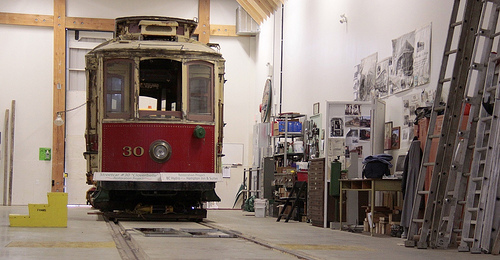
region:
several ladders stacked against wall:
[402, 0, 499, 252]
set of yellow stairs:
[9, 188, 69, 228]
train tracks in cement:
[103, 213, 310, 259]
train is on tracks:
[85, 14, 225, 219]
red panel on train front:
[96, 119, 218, 185]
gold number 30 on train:
[119, 145, 145, 156]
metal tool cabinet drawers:
[306, 160, 326, 228]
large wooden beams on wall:
[1, 3, 256, 190]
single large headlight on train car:
[148, 138, 172, 163]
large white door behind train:
[66, 25, 198, 205]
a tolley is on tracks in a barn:
[6, 2, 498, 252]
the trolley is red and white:
[82, 12, 228, 202]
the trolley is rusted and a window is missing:
[81, 18, 226, 191]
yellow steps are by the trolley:
[6, 183, 75, 234]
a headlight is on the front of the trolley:
[143, 135, 180, 165]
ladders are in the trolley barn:
[401, 2, 498, 252]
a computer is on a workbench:
[337, 148, 412, 238]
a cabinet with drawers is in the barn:
[303, 152, 330, 231]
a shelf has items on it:
[269, 108, 304, 218]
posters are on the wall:
[347, 23, 433, 113]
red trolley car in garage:
[80, 8, 233, 234]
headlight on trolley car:
[146, 137, 171, 164]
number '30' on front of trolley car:
[118, 140, 144, 160]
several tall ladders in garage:
[397, 3, 496, 258]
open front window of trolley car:
[127, 49, 191, 125]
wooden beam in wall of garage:
[47, 2, 70, 198]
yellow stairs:
[2, 187, 76, 235]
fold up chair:
[267, 173, 314, 229]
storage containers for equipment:
[235, 93, 403, 240]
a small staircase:
[6, 170, 107, 246]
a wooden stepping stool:
[3, 170, 98, 243]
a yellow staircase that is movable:
[3, 187, 98, 238]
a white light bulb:
[44, 105, 74, 135]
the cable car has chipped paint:
[76, 6, 269, 226]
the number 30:
[116, 136, 145, 163]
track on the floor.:
[120, 233, 134, 253]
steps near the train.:
[28, 201, 59, 223]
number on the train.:
[123, 144, 142, 158]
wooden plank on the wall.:
[10, 15, 52, 22]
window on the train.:
[192, 74, 207, 104]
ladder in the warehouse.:
[457, 152, 492, 234]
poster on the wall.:
[393, 33, 427, 84]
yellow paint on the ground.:
[37, 241, 107, 248]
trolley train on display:
[83, 12, 230, 222]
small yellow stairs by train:
[5, 182, 72, 233]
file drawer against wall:
[299, 149, 331, 226]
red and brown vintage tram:
[103, 27, 204, 233]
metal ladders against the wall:
[416, 13, 489, 258]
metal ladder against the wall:
[437, 23, 459, 124]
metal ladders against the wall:
[476, 85, 496, 195]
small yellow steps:
[11, 194, 69, 224]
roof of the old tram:
[114, 14, 204, 44]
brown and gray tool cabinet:
[308, 157, 334, 229]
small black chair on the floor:
[275, 174, 309, 221]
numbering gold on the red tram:
[111, 133, 145, 160]